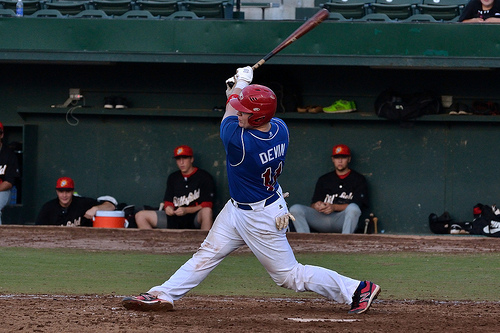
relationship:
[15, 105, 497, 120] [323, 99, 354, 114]
shelf holding sneaker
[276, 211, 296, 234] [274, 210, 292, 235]
glove in pocket